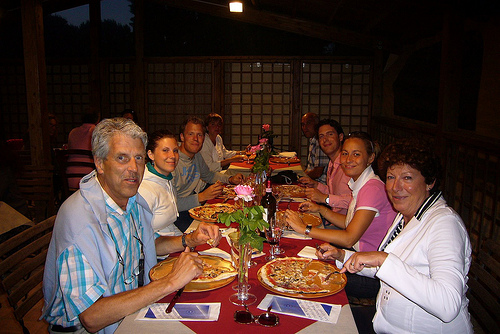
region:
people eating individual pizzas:
[66, 116, 463, 316]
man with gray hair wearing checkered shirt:
[22, 121, 195, 314]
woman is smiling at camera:
[362, 151, 484, 329]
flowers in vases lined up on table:
[224, 114, 281, 310]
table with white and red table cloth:
[155, 123, 355, 333]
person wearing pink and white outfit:
[331, 130, 402, 257]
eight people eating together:
[57, 86, 475, 325]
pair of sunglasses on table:
[225, 296, 303, 332]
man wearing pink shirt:
[312, 120, 357, 210]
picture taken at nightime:
[6, 3, 221, 55]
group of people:
[47, 67, 478, 308]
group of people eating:
[54, 71, 494, 309]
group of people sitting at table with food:
[30, 48, 481, 329]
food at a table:
[185, 141, 325, 325]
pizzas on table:
[167, 137, 315, 324]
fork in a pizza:
[235, 248, 376, 318]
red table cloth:
[168, 174, 305, 316]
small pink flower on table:
[224, 168, 281, 292]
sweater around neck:
[0, 121, 154, 303]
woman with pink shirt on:
[298, 131, 406, 258]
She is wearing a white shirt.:
[370, 163, 465, 327]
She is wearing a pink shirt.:
[325, 147, 388, 274]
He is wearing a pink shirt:
[300, 126, 346, 234]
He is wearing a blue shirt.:
[36, 140, 173, 318]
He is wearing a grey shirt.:
[165, 115, 203, 200]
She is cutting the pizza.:
[263, 250, 378, 305]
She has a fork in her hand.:
[271, 251, 374, 316]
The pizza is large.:
[253, 243, 343, 325]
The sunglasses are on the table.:
[252, 288, 335, 332]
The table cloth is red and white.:
[197, 277, 360, 332]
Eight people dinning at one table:
[53, 96, 455, 332]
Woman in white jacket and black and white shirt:
[343, 163, 470, 333]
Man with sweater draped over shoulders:
[32, 103, 187, 333]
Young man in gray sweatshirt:
[165, 107, 217, 204]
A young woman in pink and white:
[310, 134, 404, 267]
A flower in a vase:
[214, 178, 275, 314]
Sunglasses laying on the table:
[218, 298, 285, 333]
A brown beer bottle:
[259, 172, 282, 244]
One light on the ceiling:
[230, 4, 252, 20]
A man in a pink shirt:
[298, 108, 357, 216]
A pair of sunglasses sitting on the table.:
[230, 300, 285, 329]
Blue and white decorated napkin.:
[135, 297, 225, 325]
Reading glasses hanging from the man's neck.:
[107, 237, 151, 287]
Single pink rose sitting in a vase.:
[225, 179, 262, 304]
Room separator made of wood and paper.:
[159, 49, 372, 109]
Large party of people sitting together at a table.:
[81, 108, 443, 328]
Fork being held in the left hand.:
[320, 256, 397, 287]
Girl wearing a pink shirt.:
[331, 134, 387, 237]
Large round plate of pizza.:
[257, 250, 351, 297]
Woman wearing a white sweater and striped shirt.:
[360, 144, 477, 324]